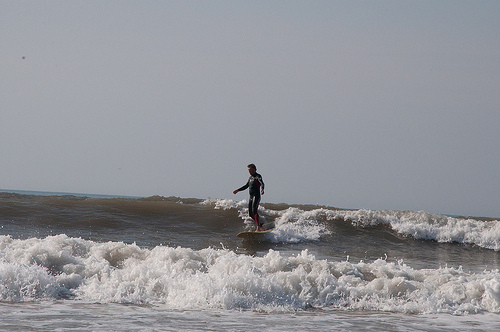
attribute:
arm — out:
[256, 173, 265, 188]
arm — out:
[233, 177, 252, 192]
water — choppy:
[44, 197, 156, 265]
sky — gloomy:
[10, 10, 477, 155]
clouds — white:
[179, 31, 493, 158]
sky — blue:
[3, 2, 498, 190]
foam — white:
[112, 244, 348, 314]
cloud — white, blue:
[7, 10, 494, 216]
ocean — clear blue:
[9, 180, 496, 323]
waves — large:
[289, 194, 456, 246]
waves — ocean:
[16, 227, 320, 307]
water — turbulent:
[1, 193, 499, 328]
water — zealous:
[22, 200, 229, 245]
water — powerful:
[57, 227, 212, 308]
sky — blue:
[19, 16, 481, 174]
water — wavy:
[14, 180, 485, 329]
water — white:
[339, 162, 486, 329]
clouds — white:
[1, 0, 496, 217]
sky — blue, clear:
[4, 1, 496, 220]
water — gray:
[51, 172, 166, 289]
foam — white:
[4, 241, 484, 315]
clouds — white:
[12, 2, 472, 157]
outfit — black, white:
[237, 171, 265, 216]